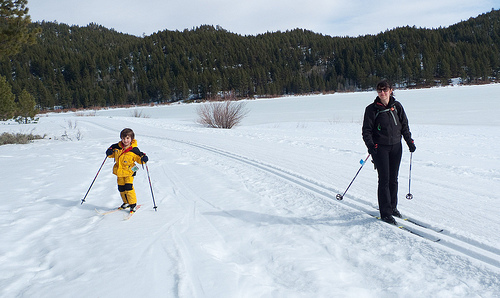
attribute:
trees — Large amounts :
[9, 12, 483, 91]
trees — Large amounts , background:
[3, 7, 483, 115]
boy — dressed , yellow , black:
[102, 123, 147, 213]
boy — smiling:
[53, 118, 163, 215]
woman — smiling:
[329, 81, 427, 225]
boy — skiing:
[75, 124, 165, 219]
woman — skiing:
[315, 82, 424, 233]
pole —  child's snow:
[82, 154, 159, 206]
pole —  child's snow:
[81, 153, 164, 211]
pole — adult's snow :
[324, 140, 424, 207]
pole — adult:
[403, 144, 419, 203]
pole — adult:
[330, 149, 373, 203]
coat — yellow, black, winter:
[104, 137, 148, 183]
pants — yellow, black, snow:
[112, 170, 140, 210]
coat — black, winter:
[356, 92, 416, 178]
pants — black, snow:
[370, 138, 401, 218]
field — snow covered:
[2, 88, 497, 296]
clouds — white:
[321, 7, 471, 44]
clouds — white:
[121, 4, 175, 26]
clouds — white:
[218, 2, 351, 42]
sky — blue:
[4, 2, 498, 52]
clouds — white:
[403, 12, 479, 37]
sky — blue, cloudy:
[6, 1, 496, 48]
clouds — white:
[99, 3, 165, 33]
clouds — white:
[80, 3, 123, 23]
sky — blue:
[4, 2, 498, 40]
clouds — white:
[24, 3, 66, 24]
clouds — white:
[343, 13, 380, 37]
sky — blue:
[1, 2, 498, 34]